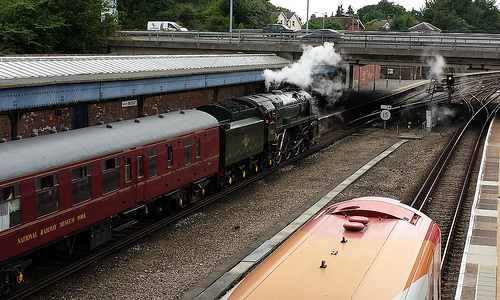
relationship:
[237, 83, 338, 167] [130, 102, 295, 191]
engine of train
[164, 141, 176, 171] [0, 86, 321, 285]
window in train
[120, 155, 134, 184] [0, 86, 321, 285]
window in train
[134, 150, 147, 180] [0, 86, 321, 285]
window in train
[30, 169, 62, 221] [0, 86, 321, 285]
window in train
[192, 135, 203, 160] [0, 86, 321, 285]
window in train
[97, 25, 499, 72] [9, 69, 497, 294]
bridge above train track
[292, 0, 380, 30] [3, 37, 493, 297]
buildings near railway station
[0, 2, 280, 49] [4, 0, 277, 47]
trees with branches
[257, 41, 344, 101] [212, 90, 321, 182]
smoke coming out of train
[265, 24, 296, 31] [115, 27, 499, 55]
black suv on bridge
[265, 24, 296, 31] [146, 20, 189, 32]
black suv ahead of van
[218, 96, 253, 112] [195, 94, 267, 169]
coal in coal car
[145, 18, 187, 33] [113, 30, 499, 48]
van on road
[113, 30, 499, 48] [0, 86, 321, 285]
road above train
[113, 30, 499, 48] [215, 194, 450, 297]
road above train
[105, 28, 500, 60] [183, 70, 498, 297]
bridge over tracks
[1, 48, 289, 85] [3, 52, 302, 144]
roof of building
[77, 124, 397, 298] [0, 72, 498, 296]
pebbles between tracks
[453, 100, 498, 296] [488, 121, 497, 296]
edge of platform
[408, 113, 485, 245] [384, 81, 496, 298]
slats between tracks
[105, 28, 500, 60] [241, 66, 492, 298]
bridge over tracks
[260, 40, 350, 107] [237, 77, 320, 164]
smoke coming from engine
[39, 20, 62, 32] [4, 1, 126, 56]
leaves on tree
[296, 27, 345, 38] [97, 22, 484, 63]
car on bridge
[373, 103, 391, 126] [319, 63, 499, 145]
sign near tracks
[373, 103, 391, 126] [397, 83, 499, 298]
sign near tracks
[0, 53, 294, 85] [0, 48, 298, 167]
roof of platform